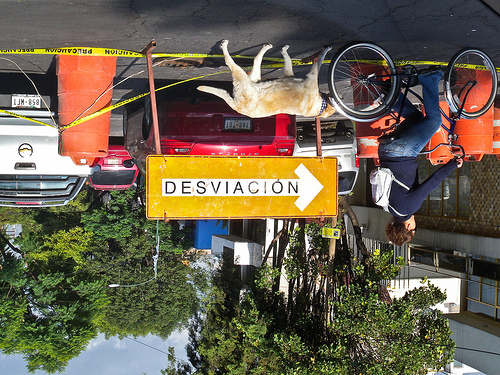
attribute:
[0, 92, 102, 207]
car — white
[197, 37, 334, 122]
dog — beige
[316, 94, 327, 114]
collar — black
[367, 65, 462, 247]
person — dark haired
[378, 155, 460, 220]
shirt — blue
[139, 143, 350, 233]
arrow — white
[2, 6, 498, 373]
picture — upside down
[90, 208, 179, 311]
post — metal, tall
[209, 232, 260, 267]
balcony — concrete, small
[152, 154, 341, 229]
sign — not upside down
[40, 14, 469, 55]
ground — caution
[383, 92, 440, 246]
person — on bicycle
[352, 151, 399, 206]
backpack — white, for back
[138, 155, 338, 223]
sign — bright yellow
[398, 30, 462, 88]
tape — yellow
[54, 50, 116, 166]
blockade — orange, barrel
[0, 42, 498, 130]
caution tape — yellow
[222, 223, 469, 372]
tree — growing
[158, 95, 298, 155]
sedan — small, red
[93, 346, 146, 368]
skies — clear, blue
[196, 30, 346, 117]
dog — brown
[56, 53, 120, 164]
traffic cone — bright orange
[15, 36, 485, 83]
tape — yellow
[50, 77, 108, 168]
cones —  large and orange 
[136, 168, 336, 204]
sign — yellow